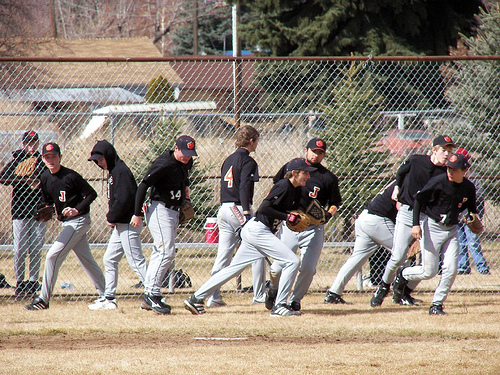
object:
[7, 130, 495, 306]
baseball players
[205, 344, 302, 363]
field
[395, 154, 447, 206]
black shirts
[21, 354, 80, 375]
grass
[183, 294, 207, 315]
black sneaker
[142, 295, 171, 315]
black sneaker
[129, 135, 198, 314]
baseball player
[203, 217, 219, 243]
red cooler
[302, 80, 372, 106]
fence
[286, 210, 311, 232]
glove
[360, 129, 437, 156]
red car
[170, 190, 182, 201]
number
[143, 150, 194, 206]
shirt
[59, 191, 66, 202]
letter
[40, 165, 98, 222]
shirt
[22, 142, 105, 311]
guy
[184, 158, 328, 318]
player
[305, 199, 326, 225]
mitt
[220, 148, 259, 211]
black shirt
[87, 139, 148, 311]
dude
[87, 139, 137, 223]
hoodie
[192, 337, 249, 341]
white plate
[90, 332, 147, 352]
dirt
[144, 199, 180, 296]
pants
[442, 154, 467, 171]
cap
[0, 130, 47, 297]
buddy